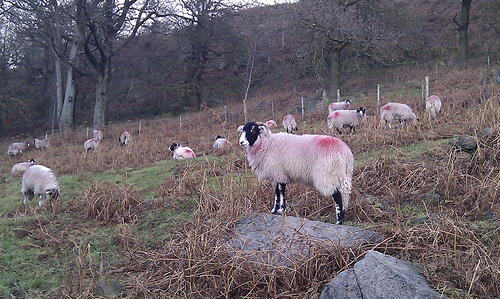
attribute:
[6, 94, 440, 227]
sheep — black, white, eating, grazing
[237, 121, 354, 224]
sheep — standing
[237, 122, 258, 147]
face — black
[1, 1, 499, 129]
trees — leaveless, tall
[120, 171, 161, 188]
grass — green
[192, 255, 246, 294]
grass — dry, dead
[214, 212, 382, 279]
rock — grey, large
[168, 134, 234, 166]
sheep — sitting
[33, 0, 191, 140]
tree — brown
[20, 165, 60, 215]
sheep — standing, grazing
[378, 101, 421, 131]
sheep — standing, grazing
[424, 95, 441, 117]
sheep — standing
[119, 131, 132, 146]
sheep — standing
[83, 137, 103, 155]
sheep — standing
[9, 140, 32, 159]
sheep — standing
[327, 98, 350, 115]
sheep — standing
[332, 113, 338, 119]
spot — red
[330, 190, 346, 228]
legs — black